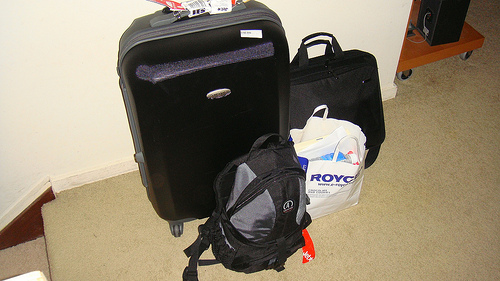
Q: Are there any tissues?
A: No, there are no tissues.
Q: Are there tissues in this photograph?
A: No, there are no tissues.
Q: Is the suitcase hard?
A: Yes, the suitcase is hard.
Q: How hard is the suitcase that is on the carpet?
A: The suitcase is hard.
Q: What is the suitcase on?
A: The suitcase is on the carpet.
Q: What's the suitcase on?
A: The suitcase is on the carpet.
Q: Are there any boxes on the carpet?
A: No, there is a suitcase on the carpet.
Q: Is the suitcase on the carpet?
A: Yes, the suitcase is on the carpet.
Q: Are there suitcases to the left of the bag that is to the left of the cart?
A: Yes, there is a suitcase to the left of the bag.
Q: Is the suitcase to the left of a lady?
A: No, the suitcase is to the left of the bag.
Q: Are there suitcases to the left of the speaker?
A: Yes, there is a suitcase to the left of the speaker.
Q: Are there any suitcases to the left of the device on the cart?
A: Yes, there is a suitcase to the left of the speaker.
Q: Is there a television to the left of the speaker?
A: No, there is a suitcase to the left of the speaker.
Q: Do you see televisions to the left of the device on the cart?
A: No, there is a suitcase to the left of the speaker.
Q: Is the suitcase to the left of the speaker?
A: Yes, the suitcase is to the left of the speaker.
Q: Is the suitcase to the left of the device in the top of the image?
A: Yes, the suitcase is to the left of the speaker.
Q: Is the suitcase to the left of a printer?
A: No, the suitcase is to the left of the speaker.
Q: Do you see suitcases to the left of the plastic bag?
A: Yes, there is a suitcase to the left of the bag.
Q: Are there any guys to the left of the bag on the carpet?
A: No, there is a suitcase to the left of the bag.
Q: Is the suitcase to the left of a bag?
A: Yes, the suitcase is to the left of a bag.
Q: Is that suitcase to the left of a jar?
A: No, the suitcase is to the left of a bag.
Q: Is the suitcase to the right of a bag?
A: No, the suitcase is to the left of a bag.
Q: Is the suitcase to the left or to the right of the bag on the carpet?
A: The suitcase is to the left of the bag.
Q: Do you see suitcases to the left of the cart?
A: Yes, there is a suitcase to the left of the cart.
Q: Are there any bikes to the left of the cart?
A: No, there is a suitcase to the left of the cart.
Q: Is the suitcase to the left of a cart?
A: Yes, the suitcase is to the left of a cart.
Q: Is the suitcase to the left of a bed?
A: No, the suitcase is to the left of a cart.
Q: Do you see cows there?
A: No, there are no cows.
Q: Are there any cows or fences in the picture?
A: No, there are no cows or fences.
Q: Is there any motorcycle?
A: No, there are no motorcycles.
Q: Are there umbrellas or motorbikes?
A: No, there are no motorbikes or umbrellas.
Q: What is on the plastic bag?
A: The letter is on the bag.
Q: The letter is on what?
A: The letter is on the bag.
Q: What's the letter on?
A: The letter is on the bag.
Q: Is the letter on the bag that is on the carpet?
A: Yes, the letter is on the bag.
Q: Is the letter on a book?
A: No, the letter is on the bag.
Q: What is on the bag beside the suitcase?
A: The letter is on the bag.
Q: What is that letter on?
A: The letter is on the bag.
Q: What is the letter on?
A: The letter is on the bag.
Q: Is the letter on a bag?
A: Yes, the letter is on a bag.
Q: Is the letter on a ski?
A: No, the letter is on a bag.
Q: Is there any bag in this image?
A: Yes, there is a bag.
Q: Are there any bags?
A: Yes, there is a bag.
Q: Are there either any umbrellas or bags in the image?
A: Yes, there is a bag.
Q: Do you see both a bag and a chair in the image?
A: No, there is a bag but no chairs.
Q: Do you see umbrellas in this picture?
A: No, there are no umbrellas.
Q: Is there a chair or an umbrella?
A: No, there are no umbrellas or chairs.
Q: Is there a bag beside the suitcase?
A: Yes, there is a bag beside the suitcase.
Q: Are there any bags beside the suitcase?
A: Yes, there is a bag beside the suitcase.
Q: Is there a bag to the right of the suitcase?
A: Yes, there is a bag to the right of the suitcase.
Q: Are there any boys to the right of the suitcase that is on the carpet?
A: No, there is a bag to the right of the suitcase.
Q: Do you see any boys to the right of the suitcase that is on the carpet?
A: No, there is a bag to the right of the suitcase.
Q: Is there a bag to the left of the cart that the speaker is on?
A: Yes, there is a bag to the left of the cart.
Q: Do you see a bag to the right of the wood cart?
A: No, the bag is to the left of the cart.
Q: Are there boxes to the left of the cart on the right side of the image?
A: No, there is a bag to the left of the cart.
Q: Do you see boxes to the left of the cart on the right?
A: No, there is a bag to the left of the cart.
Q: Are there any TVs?
A: No, there are no tvs.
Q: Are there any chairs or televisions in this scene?
A: No, there are no televisions or chairs.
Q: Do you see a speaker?
A: Yes, there is a speaker.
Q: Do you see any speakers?
A: Yes, there is a speaker.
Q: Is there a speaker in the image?
A: Yes, there is a speaker.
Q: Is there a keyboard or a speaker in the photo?
A: Yes, there is a speaker.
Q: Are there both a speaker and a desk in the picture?
A: No, there is a speaker but no desks.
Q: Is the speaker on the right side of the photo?
A: Yes, the speaker is on the right of the image.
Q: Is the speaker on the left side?
A: No, the speaker is on the right of the image.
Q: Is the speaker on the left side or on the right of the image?
A: The speaker is on the right of the image.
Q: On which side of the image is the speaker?
A: The speaker is on the right of the image.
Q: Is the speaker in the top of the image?
A: Yes, the speaker is in the top of the image.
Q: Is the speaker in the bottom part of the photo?
A: No, the speaker is in the top of the image.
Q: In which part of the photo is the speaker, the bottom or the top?
A: The speaker is in the top of the image.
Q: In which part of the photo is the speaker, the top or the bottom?
A: The speaker is in the top of the image.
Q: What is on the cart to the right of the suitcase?
A: The speaker is on the cart.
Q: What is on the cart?
A: The speaker is on the cart.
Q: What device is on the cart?
A: The device is a speaker.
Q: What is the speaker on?
A: The speaker is on the cart.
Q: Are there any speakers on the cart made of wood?
A: Yes, there is a speaker on the cart.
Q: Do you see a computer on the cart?
A: No, there is a speaker on the cart.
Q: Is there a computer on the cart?
A: No, there is a speaker on the cart.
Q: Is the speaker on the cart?
A: Yes, the speaker is on the cart.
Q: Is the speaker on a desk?
A: No, the speaker is on the cart.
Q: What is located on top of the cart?
A: The speaker is on top of the cart.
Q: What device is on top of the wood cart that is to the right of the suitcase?
A: The device is a speaker.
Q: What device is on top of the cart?
A: The device is a speaker.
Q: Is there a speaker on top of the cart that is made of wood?
A: Yes, there is a speaker on top of the cart.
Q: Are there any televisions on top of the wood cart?
A: No, there is a speaker on top of the cart.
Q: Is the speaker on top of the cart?
A: Yes, the speaker is on top of the cart.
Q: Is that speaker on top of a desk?
A: No, the speaker is on top of the cart.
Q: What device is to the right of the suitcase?
A: The device is a speaker.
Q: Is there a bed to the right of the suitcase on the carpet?
A: No, there is a speaker to the right of the suitcase.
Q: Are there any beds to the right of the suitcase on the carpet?
A: No, there is a speaker to the right of the suitcase.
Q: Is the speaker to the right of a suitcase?
A: Yes, the speaker is to the right of a suitcase.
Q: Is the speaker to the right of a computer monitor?
A: No, the speaker is to the right of a suitcase.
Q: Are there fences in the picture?
A: No, there are no fences.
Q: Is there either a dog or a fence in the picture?
A: No, there are no fences or dogs.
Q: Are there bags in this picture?
A: Yes, there is a bag.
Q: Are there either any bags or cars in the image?
A: Yes, there is a bag.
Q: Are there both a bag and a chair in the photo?
A: No, there is a bag but no chairs.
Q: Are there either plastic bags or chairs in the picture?
A: Yes, there is a plastic bag.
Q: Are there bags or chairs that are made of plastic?
A: Yes, the bag is made of plastic.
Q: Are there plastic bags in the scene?
A: Yes, there is a bag that is made of plastic.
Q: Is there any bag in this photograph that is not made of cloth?
A: Yes, there is a bag that is made of plastic.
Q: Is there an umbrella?
A: No, there are no umbrellas.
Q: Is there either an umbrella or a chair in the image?
A: No, there are no umbrellas or chairs.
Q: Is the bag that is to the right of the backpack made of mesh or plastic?
A: The bag is made of plastic.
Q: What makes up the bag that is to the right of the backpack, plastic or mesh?
A: The bag is made of plastic.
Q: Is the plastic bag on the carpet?
A: Yes, the bag is on the carpet.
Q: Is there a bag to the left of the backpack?
A: No, the bag is to the right of the backpack.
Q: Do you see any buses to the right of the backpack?
A: No, there is a bag to the right of the backpack.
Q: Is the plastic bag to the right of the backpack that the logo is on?
A: Yes, the bag is to the right of the backpack.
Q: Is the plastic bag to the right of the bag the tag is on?
A: Yes, the bag is to the right of the backpack.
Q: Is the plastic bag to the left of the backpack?
A: No, the bag is to the right of the backpack.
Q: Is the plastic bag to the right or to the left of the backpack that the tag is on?
A: The bag is to the right of the backpack.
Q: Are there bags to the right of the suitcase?
A: Yes, there is a bag to the right of the suitcase.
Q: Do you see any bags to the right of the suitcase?
A: Yes, there is a bag to the right of the suitcase.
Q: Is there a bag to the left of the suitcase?
A: No, the bag is to the right of the suitcase.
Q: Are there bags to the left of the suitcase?
A: No, the bag is to the right of the suitcase.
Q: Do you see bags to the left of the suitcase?
A: No, the bag is to the right of the suitcase.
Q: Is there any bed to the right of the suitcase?
A: No, there is a bag to the right of the suitcase.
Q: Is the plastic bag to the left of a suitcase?
A: No, the bag is to the right of a suitcase.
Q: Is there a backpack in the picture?
A: Yes, there is a backpack.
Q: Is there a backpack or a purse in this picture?
A: Yes, there is a backpack.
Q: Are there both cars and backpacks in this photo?
A: No, there is a backpack but no cars.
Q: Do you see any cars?
A: No, there are no cars.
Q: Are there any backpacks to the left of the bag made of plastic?
A: Yes, there is a backpack to the left of the bag.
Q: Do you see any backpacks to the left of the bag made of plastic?
A: Yes, there is a backpack to the left of the bag.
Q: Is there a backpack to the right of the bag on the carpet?
A: No, the backpack is to the left of the bag.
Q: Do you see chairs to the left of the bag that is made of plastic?
A: No, there is a backpack to the left of the bag.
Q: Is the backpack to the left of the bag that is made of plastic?
A: Yes, the backpack is to the left of the bag.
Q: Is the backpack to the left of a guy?
A: No, the backpack is to the left of the bag.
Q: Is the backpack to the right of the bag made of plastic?
A: No, the backpack is to the left of the bag.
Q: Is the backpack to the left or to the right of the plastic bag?
A: The backpack is to the left of the bag.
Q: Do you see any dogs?
A: No, there are no dogs.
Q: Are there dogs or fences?
A: No, there are no dogs or fences.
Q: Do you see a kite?
A: No, there are no kites.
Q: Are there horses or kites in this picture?
A: No, there are no kites or horses.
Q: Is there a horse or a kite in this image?
A: No, there are no kites or horses.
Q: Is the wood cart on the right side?
A: Yes, the cart is on the right of the image.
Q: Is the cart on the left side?
A: No, the cart is on the right of the image.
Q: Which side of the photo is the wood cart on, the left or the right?
A: The cart is on the right of the image.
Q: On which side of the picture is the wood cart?
A: The cart is on the right of the image.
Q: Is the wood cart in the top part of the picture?
A: Yes, the cart is in the top of the image.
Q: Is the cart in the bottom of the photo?
A: No, the cart is in the top of the image.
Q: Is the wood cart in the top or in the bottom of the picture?
A: The cart is in the top of the image.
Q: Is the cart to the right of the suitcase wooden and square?
A: Yes, the cart is wooden and square.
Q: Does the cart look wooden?
A: Yes, the cart is wooden.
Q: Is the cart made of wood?
A: Yes, the cart is made of wood.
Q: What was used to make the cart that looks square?
A: The cart is made of wood.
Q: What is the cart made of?
A: The cart is made of wood.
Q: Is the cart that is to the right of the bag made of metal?
A: No, the cart is made of wood.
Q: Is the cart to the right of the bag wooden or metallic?
A: The cart is wooden.